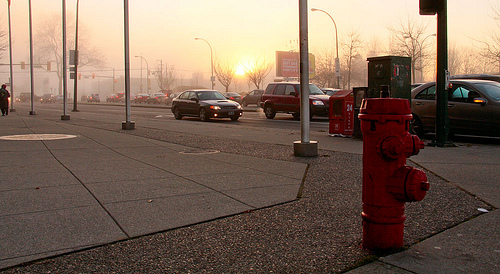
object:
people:
[199, 92, 218, 100]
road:
[0, 100, 499, 274]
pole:
[62, 0, 67, 116]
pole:
[124, 0, 131, 123]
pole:
[299, 0, 311, 144]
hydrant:
[357, 84, 430, 252]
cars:
[86, 93, 100, 103]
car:
[242, 89, 264, 107]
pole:
[74, 0, 79, 111]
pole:
[8, 0, 14, 109]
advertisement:
[275, 50, 315, 77]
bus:
[171, 90, 243, 122]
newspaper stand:
[329, 90, 354, 138]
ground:
[328, 153, 343, 168]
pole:
[28, 1, 34, 112]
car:
[411, 79, 500, 133]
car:
[259, 82, 330, 121]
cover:
[179, 149, 221, 155]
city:
[0, 0, 499, 274]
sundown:
[233, 60, 257, 78]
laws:
[68, 50, 75, 79]